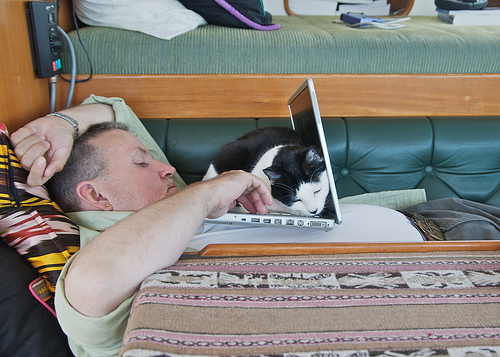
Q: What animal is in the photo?
A: Cat.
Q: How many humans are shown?
A: One.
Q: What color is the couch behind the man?
A: Green.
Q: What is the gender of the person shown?
A: Male.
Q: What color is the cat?
A: Black and white.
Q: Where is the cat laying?
A: Laptop.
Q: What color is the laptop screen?
A: Black.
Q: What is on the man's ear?
A: Earring.